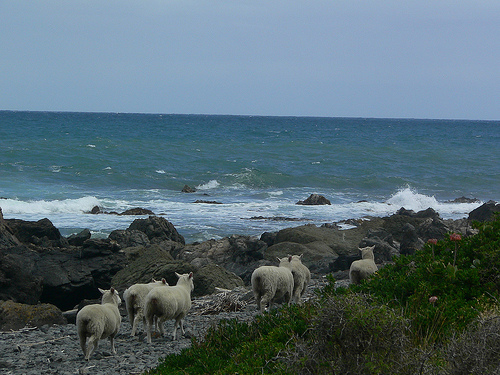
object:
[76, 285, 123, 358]
sheep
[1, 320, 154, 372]
trail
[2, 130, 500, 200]
water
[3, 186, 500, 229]
shore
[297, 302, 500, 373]
grass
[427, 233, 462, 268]
flowers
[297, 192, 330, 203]
rock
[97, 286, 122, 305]
head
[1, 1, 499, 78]
sky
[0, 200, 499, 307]
rock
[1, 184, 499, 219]
waves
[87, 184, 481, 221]
rocks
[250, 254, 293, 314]
sheep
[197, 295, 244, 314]
sticks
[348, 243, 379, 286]
sheep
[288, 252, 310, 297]
sheep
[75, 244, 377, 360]
sheeps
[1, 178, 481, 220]
foam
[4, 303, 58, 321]
moss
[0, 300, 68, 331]
rock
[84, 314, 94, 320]
tail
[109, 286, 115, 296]
ear